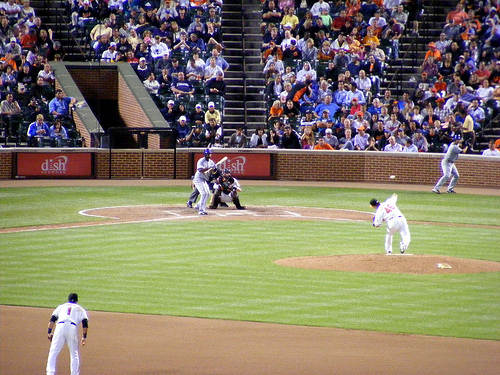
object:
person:
[353, 182, 424, 261]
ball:
[378, 171, 403, 186]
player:
[31, 278, 117, 374]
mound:
[380, 247, 417, 267]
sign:
[13, 145, 97, 177]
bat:
[204, 153, 228, 174]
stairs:
[219, 104, 270, 115]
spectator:
[6, 6, 492, 183]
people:
[27, 112, 53, 141]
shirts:
[28, 119, 51, 144]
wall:
[6, 138, 499, 182]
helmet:
[199, 145, 216, 157]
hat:
[368, 196, 384, 209]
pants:
[380, 214, 416, 253]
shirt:
[370, 193, 401, 226]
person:
[193, 141, 218, 216]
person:
[423, 118, 473, 198]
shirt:
[438, 142, 466, 165]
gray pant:
[421, 157, 464, 196]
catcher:
[207, 167, 248, 211]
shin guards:
[209, 186, 225, 209]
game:
[3, 8, 493, 374]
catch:
[217, 174, 234, 191]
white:
[57, 327, 77, 335]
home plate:
[201, 202, 263, 221]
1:
[61, 305, 76, 317]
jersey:
[52, 304, 91, 331]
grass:
[150, 240, 267, 315]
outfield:
[45, 230, 473, 321]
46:
[376, 196, 400, 218]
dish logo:
[35, 153, 73, 175]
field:
[2, 176, 497, 367]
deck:
[160, 142, 283, 180]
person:
[423, 39, 443, 61]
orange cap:
[427, 38, 436, 53]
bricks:
[95, 172, 111, 176]